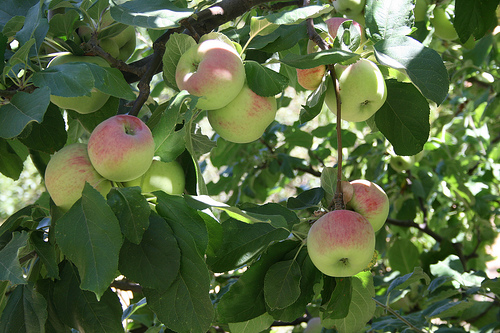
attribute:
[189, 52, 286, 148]
apples — red, unripe, 10, fresh, lots, colorful, ripe, opposite, growing, large, stemmed, t-shaped, two by two, pink, shaded, green, bunched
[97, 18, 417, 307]
tree — damaged, thicker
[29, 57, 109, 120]
leaves — drooping, green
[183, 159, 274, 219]
sun — shining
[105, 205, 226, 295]
foilage — extensive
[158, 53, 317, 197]
fruits — purple, green, here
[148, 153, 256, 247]
shadows — cast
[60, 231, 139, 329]
leaf — eaten, green